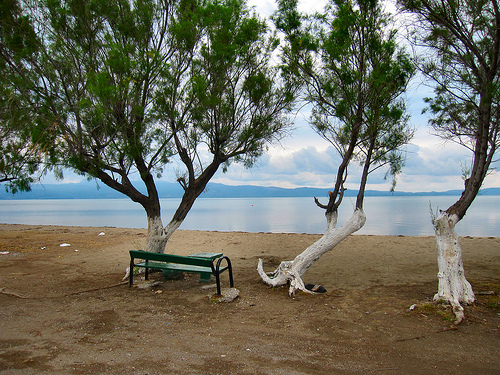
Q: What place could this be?
A: It is a park.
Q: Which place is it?
A: It is a park.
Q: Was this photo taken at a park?
A: Yes, it was taken in a park.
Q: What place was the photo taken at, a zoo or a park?
A: It was taken at a park.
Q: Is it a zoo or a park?
A: It is a park.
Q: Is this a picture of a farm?
A: No, the picture is showing a park.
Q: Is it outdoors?
A: Yes, it is outdoors.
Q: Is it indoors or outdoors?
A: It is outdoors.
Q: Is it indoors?
A: No, it is outdoors.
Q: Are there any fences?
A: No, there are no fences.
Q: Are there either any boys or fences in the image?
A: No, there are no fences or boys.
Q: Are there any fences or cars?
A: No, there are no fences or cars.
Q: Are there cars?
A: No, there are no cars.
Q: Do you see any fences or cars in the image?
A: No, there are no cars or fences.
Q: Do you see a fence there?
A: No, there are no fences.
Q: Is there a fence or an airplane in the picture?
A: No, there are no fences or airplanes.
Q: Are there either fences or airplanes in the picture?
A: No, there are no fences or airplanes.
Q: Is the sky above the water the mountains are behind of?
A: Yes, the sky is above the water.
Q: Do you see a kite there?
A: No, there are no kites.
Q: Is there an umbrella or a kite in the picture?
A: No, there are no kites or umbrellas.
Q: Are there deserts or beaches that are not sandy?
A: No, there is a beach but it is sandy.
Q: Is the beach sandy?
A: Yes, the beach is sandy.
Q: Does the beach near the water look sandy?
A: Yes, the beach is sandy.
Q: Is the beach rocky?
A: No, the beach is sandy.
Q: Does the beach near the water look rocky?
A: No, the beach is sandy.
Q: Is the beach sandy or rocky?
A: The beach is sandy.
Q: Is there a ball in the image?
A: No, there are no balls.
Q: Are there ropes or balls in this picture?
A: No, there are no balls or ropes.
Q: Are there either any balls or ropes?
A: No, there are no balls or ropes.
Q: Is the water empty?
A: Yes, the water is empty.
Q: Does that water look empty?
A: Yes, the water is empty.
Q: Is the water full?
A: No, the water is empty.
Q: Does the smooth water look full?
A: No, the water is empty.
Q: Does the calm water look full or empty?
A: The water is empty.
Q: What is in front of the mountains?
A: The water is in front of the mountains.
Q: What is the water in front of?
A: The water is in front of the mountains.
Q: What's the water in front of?
A: The water is in front of the mountains.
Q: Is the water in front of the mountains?
A: Yes, the water is in front of the mountains.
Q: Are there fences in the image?
A: No, there are no fences.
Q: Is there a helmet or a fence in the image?
A: No, there are no fences or helmets.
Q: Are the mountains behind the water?
A: Yes, the mountains are behind the water.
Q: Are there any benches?
A: Yes, there is a bench.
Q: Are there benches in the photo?
A: Yes, there is a bench.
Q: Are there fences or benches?
A: Yes, there is a bench.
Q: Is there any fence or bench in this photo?
A: Yes, there is a bench.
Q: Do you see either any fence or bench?
A: Yes, there is a bench.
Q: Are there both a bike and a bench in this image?
A: No, there is a bench but no bikes.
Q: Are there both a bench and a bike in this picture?
A: No, there is a bench but no bikes.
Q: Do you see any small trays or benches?
A: Yes, there is a small bench.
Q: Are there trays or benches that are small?
A: Yes, the bench is small.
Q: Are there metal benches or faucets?
A: Yes, there is a metal bench.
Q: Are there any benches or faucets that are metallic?
A: Yes, the bench is metallic.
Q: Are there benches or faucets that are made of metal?
A: Yes, the bench is made of metal.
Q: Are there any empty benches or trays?
A: Yes, there is an empty bench.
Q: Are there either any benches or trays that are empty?
A: Yes, the bench is empty.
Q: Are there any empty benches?
A: Yes, there is an empty bench.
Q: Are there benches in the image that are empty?
A: Yes, there is an empty bench.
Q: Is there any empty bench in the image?
A: Yes, there is an empty bench.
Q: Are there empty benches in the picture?
A: Yes, there is an empty bench.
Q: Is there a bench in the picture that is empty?
A: Yes, there is a bench that is empty.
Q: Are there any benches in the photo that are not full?
A: Yes, there is a empty bench.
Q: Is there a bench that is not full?
A: Yes, there is a empty bench.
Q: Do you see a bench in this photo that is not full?
A: Yes, there is a empty bench.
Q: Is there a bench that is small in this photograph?
A: Yes, there is a small bench.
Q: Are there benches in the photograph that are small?
A: Yes, there is a bench that is small.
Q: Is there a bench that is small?
A: Yes, there is a bench that is small.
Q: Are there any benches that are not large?
A: Yes, there is a small bench.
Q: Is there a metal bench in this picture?
A: Yes, there is a metal bench.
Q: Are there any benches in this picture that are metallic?
A: Yes, there is a bench that is metallic.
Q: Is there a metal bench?
A: Yes, there is a bench that is made of metal.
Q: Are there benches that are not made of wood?
A: Yes, there is a bench that is made of metal.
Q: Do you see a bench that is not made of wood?
A: Yes, there is a bench that is made of metal.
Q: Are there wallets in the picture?
A: No, there are no wallets.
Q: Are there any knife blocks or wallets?
A: No, there are no wallets or knife blocks.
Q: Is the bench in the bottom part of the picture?
A: Yes, the bench is in the bottom of the image.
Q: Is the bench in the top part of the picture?
A: No, the bench is in the bottom of the image.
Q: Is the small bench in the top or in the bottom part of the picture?
A: The bench is in the bottom of the image.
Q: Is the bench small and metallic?
A: Yes, the bench is small and metallic.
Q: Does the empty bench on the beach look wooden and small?
A: No, the bench is small but metallic.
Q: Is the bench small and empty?
A: Yes, the bench is small and empty.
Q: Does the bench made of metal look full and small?
A: No, the bench is small but empty.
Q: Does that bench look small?
A: Yes, the bench is small.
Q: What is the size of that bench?
A: The bench is small.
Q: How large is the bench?
A: The bench is small.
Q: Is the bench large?
A: No, the bench is small.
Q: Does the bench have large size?
A: No, the bench is small.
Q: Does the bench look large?
A: No, the bench is small.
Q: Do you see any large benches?
A: No, there is a bench but it is small.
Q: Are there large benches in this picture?
A: No, there is a bench but it is small.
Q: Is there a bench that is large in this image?
A: No, there is a bench but it is small.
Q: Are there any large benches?
A: No, there is a bench but it is small.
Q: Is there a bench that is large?
A: No, there is a bench but it is small.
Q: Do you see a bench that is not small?
A: No, there is a bench but it is small.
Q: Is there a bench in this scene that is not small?
A: No, there is a bench but it is small.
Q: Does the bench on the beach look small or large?
A: The bench is small.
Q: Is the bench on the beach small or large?
A: The bench is small.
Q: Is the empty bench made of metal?
A: Yes, the bench is made of metal.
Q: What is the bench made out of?
A: The bench is made of metal.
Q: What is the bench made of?
A: The bench is made of metal.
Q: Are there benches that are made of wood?
A: No, there is a bench but it is made of metal.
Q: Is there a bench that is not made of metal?
A: No, there is a bench but it is made of metal.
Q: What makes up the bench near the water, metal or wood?
A: The bench is made of metal.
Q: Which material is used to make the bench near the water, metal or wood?
A: The bench is made of metal.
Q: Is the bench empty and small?
A: Yes, the bench is empty and small.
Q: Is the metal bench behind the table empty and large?
A: No, the bench is empty but small.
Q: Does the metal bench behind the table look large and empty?
A: No, the bench is empty but small.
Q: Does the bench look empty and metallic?
A: Yes, the bench is empty and metallic.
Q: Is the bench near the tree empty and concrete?
A: No, the bench is empty but metallic.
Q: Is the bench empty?
A: Yes, the bench is empty.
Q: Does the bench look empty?
A: Yes, the bench is empty.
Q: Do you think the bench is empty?
A: Yes, the bench is empty.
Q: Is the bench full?
A: No, the bench is empty.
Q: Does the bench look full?
A: No, the bench is empty.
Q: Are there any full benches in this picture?
A: No, there is a bench but it is empty.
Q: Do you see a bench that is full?
A: No, there is a bench but it is empty.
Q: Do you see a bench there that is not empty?
A: No, there is a bench but it is empty.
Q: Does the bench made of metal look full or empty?
A: The bench is empty.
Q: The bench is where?
A: The bench is on the beach.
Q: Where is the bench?
A: The bench is on the beach.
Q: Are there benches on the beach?
A: Yes, there is a bench on the beach.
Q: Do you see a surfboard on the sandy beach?
A: No, there is a bench on the beach.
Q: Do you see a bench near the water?
A: Yes, there is a bench near the water.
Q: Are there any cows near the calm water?
A: No, there is a bench near the water.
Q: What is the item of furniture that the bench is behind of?
A: The piece of furniture is a table.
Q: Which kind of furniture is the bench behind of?
A: The bench is behind the table.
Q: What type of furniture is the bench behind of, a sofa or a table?
A: The bench is behind a table.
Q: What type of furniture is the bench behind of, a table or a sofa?
A: The bench is behind a table.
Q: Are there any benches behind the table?
A: Yes, there is a bench behind the table.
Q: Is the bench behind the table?
A: Yes, the bench is behind the table.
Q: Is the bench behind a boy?
A: No, the bench is behind the table.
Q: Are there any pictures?
A: No, there are no pictures.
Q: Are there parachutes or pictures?
A: No, there are no pictures or parachutes.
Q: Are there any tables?
A: Yes, there is a table.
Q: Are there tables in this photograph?
A: Yes, there is a table.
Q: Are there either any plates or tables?
A: Yes, there is a table.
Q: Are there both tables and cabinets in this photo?
A: No, there is a table but no cabinets.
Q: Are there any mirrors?
A: No, there are no mirrors.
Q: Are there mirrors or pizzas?
A: No, there are no mirrors or pizzas.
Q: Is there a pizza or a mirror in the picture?
A: No, there are no mirrors or pizzas.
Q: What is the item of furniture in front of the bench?
A: The piece of furniture is a table.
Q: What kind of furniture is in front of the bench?
A: The piece of furniture is a table.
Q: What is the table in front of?
A: The table is in front of the bench.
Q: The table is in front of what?
A: The table is in front of the bench.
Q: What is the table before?
A: The table is in front of the bench.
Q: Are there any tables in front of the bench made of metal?
A: Yes, there is a table in front of the bench.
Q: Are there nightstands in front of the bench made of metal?
A: No, there is a table in front of the bench.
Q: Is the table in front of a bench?
A: Yes, the table is in front of a bench.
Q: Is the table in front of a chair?
A: No, the table is in front of a bench.